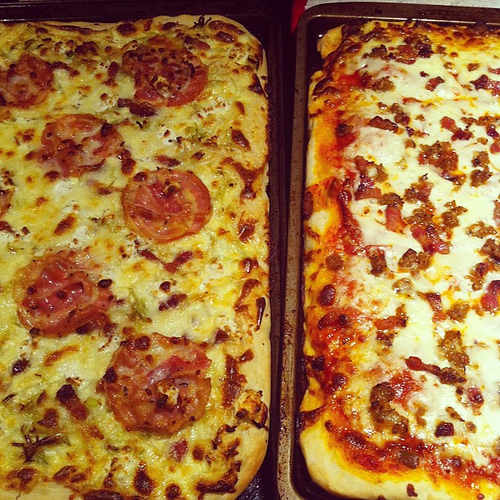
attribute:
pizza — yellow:
[0, 14, 498, 499]